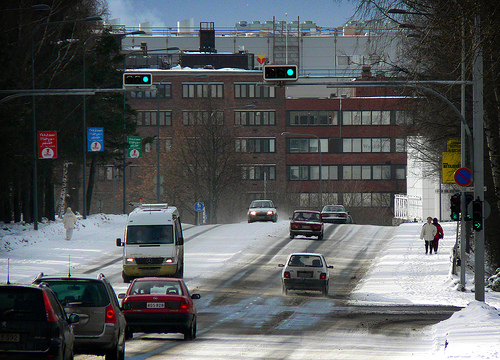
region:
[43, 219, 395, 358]
a snowy street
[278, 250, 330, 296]
a white car on street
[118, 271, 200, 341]
a red car on street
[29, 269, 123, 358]
a grey van on street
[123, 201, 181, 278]
a white commercial truck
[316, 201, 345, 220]
a white car on street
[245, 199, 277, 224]
a white car on street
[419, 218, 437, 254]
a pedestrian in snow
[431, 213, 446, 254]
a pedestrian in snow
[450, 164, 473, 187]
a do not enter sign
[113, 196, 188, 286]
The van is yellow and white.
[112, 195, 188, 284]
The van's headlights are on.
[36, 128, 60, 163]
The sign is red and white.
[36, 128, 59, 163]
The sign is rectangular.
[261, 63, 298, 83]
The traffic light is green.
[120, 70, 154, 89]
The traffic light is green.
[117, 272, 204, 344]
The car is red.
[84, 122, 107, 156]
The sign is red, white and blue.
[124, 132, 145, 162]
The sign is green, white and red.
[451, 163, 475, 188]
The sign is round.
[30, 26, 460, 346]
Traffic is on a city street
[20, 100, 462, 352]
Snow is covering a city street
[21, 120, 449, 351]
People are driving with caution on a street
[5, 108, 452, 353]
Cars are moving slowly because of snow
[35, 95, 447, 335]
Cars have their headlights on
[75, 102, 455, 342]
Slippery streets in a city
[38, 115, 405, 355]
Hazardous driving conditions in a city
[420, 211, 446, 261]
People are walking in the snow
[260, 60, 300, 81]
A traffic light is green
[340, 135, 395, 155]
The windows of a building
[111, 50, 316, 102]
Two green street lights above the road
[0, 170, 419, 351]
A number of vehicles driving on the road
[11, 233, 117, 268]
Freshly fallen snow on the sidewalk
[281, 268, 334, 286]
Two red break lights on the car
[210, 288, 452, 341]
A black shadow cast on the ground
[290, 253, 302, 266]
The driver of the small white vehicle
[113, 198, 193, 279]
A large white and yellow van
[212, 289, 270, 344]
Small dashed white lines in the middle of the road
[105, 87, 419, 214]
A red brick building in the distance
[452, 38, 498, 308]
A tall metal pole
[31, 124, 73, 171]
the flag is red and white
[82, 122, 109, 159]
the flag is blue and white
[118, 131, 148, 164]
the flag is green and white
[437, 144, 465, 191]
the sign is yellow and black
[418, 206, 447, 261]
these two are walking together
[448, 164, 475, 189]
the sign is blue and red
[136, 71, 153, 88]
the light is green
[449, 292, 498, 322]
the snow is piled by the pole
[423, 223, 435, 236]
the coat is white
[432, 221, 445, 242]
the coat is red